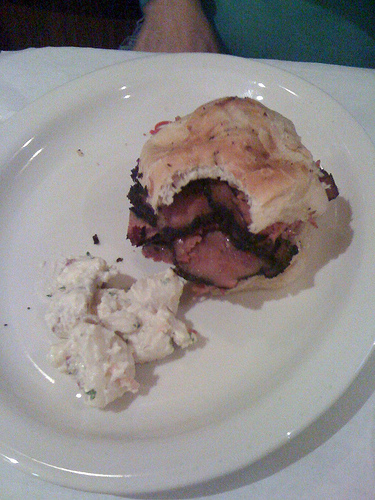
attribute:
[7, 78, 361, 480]
plate — round, white, shiny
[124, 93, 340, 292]
sandwich — meat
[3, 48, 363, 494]
plate — shiny, white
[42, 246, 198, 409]
salad — white, potato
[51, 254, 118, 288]
salad — white, potato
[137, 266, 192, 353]
salad — potato, white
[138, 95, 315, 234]
biscuit — brown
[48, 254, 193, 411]
food — white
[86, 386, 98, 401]
part — green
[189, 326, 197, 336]
part — orange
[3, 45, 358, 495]
table cloth — white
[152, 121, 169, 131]
thing — orange